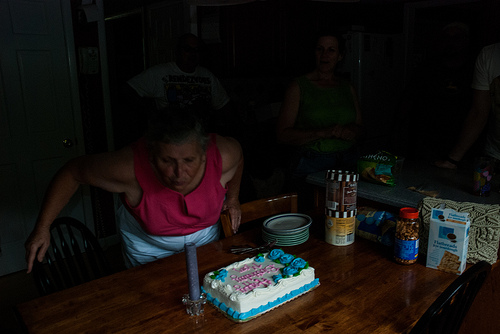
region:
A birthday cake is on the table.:
[206, 248, 318, 323]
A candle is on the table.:
[181, 240, 203, 317]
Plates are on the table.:
[263, 211, 317, 246]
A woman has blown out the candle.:
[153, 132, 206, 192]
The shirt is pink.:
[155, 196, 213, 223]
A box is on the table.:
[426, 207, 473, 273]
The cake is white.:
[241, 291, 268, 305]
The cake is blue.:
[286, 255, 303, 267]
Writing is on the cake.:
[231, 260, 274, 291]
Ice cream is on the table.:
[328, 168, 360, 245]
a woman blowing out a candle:
[30, 109, 265, 265]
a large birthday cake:
[170, 237, 337, 322]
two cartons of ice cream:
[319, 168, 367, 262]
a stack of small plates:
[256, 209, 314, 246]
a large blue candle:
[170, 236, 210, 318]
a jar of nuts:
[384, 199, 420, 276]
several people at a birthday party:
[109, 28, 498, 183]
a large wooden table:
[17, 180, 474, 327]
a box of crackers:
[424, 195, 481, 285]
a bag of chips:
[340, 129, 415, 207]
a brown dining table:
[336, 276, 386, 319]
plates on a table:
[278, 213, 312, 255]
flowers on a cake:
[276, 245, 306, 280]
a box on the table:
[433, 233, 450, 287]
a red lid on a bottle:
[396, 201, 428, 226]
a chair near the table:
[62, 206, 107, 287]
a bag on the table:
[361, 150, 398, 188]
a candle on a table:
[178, 229, 210, 276]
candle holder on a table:
[179, 293, 215, 323]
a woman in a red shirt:
[145, 126, 219, 230]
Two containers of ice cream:
[319, 167, 359, 247]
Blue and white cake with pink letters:
[196, 244, 324, 321]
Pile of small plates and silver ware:
[222, 209, 317, 257]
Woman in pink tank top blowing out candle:
[21, 112, 249, 324]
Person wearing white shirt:
[107, 30, 240, 133]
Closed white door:
[4, 1, 98, 272]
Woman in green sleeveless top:
[272, 28, 366, 190]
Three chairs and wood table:
[9, 189, 493, 330]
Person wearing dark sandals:
[425, 29, 498, 184]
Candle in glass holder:
[176, 241, 211, 322]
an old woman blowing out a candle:
[44, 138, 284, 313]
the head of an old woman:
[157, 111, 207, 188]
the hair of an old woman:
[170, 120, 193, 137]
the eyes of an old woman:
[157, 151, 201, 165]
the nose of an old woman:
[172, 157, 187, 172]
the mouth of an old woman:
[170, 171, 181, 181]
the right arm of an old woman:
[8, 147, 145, 255]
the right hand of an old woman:
[19, 226, 58, 267]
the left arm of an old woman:
[214, 144, 258, 239]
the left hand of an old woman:
[221, 198, 246, 226]